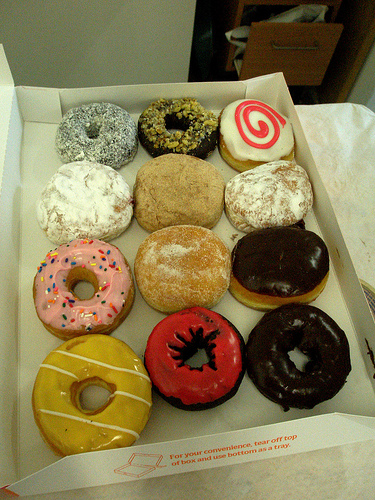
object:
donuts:
[135, 96, 221, 159]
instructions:
[168, 434, 298, 468]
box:
[0, 46, 374, 490]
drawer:
[227, 2, 344, 88]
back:
[2, 2, 372, 74]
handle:
[268, 39, 325, 53]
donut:
[241, 298, 354, 415]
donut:
[27, 238, 137, 339]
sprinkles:
[36, 239, 125, 326]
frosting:
[31, 240, 137, 332]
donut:
[35, 159, 137, 241]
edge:
[5, 72, 298, 96]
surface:
[5, 0, 192, 83]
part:
[50, 20, 134, 63]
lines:
[37, 408, 141, 441]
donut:
[29, 333, 155, 456]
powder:
[230, 164, 317, 229]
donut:
[222, 160, 317, 236]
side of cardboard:
[3, 414, 374, 496]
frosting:
[243, 303, 354, 408]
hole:
[283, 336, 319, 376]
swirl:
[228, 98, 290, 150]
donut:
[218, 96, 299, 173]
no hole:
[67, 177, 106, 217]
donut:
[144, 306, 251, 414]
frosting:
[146, 305, 249, 410]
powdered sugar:
[40, 159, 133, 242]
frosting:
[219, 98, 298, 164]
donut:
[137, 95, 218, 159]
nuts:
[196, 117, 217, 131]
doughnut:
[53, 102, 139, 165]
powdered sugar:
[55, 107, 139, 160]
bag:
[227, 0, 344, 87]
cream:
[144, 305, 243, 405]